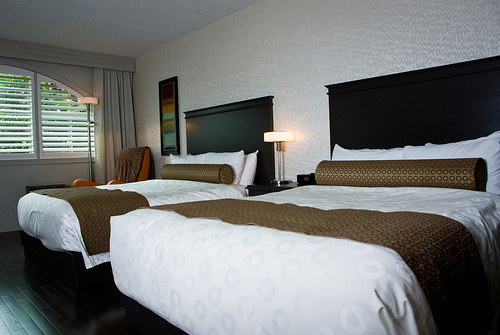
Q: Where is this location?
A: Hotel room.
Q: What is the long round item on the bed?
A: Pillow.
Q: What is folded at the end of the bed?
A: Blanket.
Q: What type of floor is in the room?
A: Hardwood.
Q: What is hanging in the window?
A: Blinds.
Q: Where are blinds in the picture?
A: In a window.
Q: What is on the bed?
A: Brown roll.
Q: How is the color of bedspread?
A: White.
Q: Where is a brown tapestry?
A: On a bed.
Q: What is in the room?
A: Two beds with white bedspreads.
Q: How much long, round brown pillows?
A: Two.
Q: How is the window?
A: It has open blinds.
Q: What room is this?
A: Room of a hotel.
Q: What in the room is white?
A: The wall.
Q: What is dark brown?
A: Headboard of bed.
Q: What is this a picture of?
A: A hotel room.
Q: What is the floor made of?
A: Wood.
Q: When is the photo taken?
A: Daytime.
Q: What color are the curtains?
A: White.